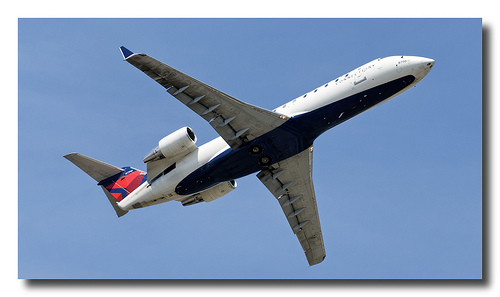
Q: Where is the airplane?
A: The sky.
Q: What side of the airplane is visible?
A: The bottom.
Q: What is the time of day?
A: Mid day.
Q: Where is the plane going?
A: Up.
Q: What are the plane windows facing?
A: The sky.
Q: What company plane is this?
A: Jet blue.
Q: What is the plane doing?
A: Flying.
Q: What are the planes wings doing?
A: Making the plane fly.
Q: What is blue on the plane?
A: The underbelly.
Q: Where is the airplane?
A: In the sky.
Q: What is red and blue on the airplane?
A: Tail.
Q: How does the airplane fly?
A: Wings.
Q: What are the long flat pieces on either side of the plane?
A: Wings.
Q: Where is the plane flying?
A: In the sky.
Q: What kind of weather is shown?
A: Clear and sunny.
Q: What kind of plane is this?
A: Passenger plane.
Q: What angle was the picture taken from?
A: Underside of the plane.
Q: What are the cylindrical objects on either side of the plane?
A: Engines.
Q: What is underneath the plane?
A: Blue and white paint.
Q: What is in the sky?
A: A plane.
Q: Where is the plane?
A: In the sky.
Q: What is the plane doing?
A: Flying.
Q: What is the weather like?
A: Clear.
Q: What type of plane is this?
A: Passenger.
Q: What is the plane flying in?
A: Clear skies.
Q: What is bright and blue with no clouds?
A: The sky.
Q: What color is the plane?
A: White.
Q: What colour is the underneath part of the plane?
A: Black.